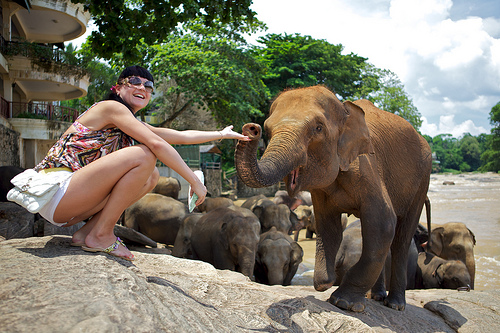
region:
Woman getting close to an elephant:
[8, 49, 484, 317]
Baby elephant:
[210, 58, 490, 331]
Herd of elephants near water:
[80, 67, 483, 326]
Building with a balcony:
[2, 40, 98, 248]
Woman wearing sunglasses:
[29, 59, 196, 266]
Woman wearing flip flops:
[17, 67, 223, 281]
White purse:
[4, 144, 86, 239]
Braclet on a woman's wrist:
[209, 119, 228, 150]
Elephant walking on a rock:
[201, 69, 447, 331]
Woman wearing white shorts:
[7, 47, 226, 312]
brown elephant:
[243, 81, 448, 302]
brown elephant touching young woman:
[236, 87, 438, 300]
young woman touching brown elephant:
[18, 61, 250, 268]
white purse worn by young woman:
[11, 170, 50, 212]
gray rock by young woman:
[20, 265, 227, 329]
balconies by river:
[13, 7, 69, 117]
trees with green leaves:
[120, 16, 325, 62]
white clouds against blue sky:
[304, 4, 488, 36]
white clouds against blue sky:
[416, 14, 485, 120]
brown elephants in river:
[436, 199, 489, 300]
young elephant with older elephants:
[222, 75, 447, 315]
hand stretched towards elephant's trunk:
[212, 115, 268, 170]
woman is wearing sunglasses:
[87, 67, 175, 127]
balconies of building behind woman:
[7, 33, 161, 144]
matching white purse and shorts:
[10, 151, 91, 255]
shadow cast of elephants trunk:
[237, 267, 306, 331]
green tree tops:
[163, 9, 367, 99]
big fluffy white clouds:
[307, 6, 494, 126]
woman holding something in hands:
[176, 162, 214, 213]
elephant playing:
[218, 76, 458, 321]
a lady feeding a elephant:
[34, 66, 254, 272]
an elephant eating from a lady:
[226, 60, 453, 319]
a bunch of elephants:
[169, 169, 369, 284]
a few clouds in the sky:
[374, 13, 455, 93]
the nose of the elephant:
[236, 121, 266, 186]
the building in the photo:
[6, 20, 81, 111]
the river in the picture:
[444, 161, 496, 223]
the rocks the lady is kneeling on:
[66, 283, 305, 314]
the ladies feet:
[76, 233, 140, 260]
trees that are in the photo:
[166, 0, 383, 104]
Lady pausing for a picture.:
[3, 61, 250, 259]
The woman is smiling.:
[105, 60, 160, 125]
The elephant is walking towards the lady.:
[235, 80, 430, 305]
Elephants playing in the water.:
[150, 170, 476, 285]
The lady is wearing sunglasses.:
[121, 72, 156, 88]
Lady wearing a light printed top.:
[30, 96, 130, 167]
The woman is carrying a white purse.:
[5, 165, 60, 210]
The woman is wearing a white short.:
[35, 165, 70, 230]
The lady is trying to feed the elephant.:
[216, 110, 276, 201]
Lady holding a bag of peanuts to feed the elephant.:
[185, 161, 210, 216]